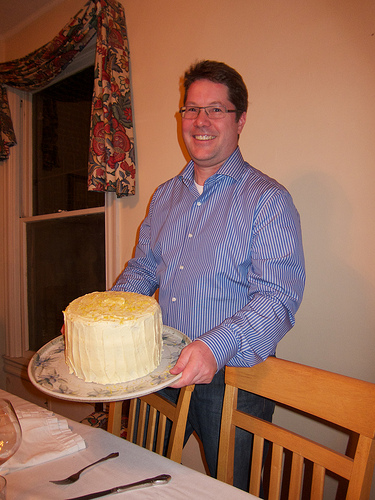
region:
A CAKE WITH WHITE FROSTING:
[52, 281, 176, 388]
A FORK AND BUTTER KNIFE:
[47, 442, 181, 497]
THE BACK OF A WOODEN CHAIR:
[208, 349, 371, 494]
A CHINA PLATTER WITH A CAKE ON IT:
[21, 284, 200, 408]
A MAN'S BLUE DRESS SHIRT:
[104, 147, 309, 377]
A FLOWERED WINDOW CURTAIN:
[6, 5, 137, 204]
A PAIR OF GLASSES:
[175, 99, 247, 125]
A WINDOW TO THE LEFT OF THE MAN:
[6, 137, 126, 360]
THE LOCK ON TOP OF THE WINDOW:
[44, 204, 79, 217]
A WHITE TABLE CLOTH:
[86, 429, 186, 498]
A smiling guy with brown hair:
[139, 57, 291, 287]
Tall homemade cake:
[61, 284, 166, 384]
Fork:
[46, 450, 122, 483]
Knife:
[86, 472, 171, 498]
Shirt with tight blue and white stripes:
[159, 165, 312, 287]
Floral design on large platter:
[31, 352, 65, 388]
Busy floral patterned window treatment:
[75, 6, 136, 136]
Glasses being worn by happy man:
[176, 102, 248, 120]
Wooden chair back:
[224, 362, 352, 498]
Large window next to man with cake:
[19, 45, 110, 350]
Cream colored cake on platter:
[55, 278, 168, 389]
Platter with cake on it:
[21, 308, 211, 404]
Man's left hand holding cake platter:
[167, 324, 224, 399]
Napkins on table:
[20, 407, 89, 467]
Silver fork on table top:
[41, 429, 120, 485]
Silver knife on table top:
[87, 471, 161, 497]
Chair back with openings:
[210, 378, 347, 496]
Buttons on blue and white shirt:
[164, 183, 213, 317]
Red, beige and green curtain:
[65, 6, 159, 213]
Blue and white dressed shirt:
[137, 147, 314, 363]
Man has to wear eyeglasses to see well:
[177, 99, 237, 120]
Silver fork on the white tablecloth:
[45, 444, 120, 486]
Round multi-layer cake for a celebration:
[54, 286, 168, 387]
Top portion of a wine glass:
[0, 396, 23, 475]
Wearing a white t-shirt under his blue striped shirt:
[186, 176, 213, 196]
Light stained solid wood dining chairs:
[217, 356, 372, 499]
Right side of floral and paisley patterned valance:
[89, 4, 134, 196]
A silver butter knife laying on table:
[62, 478, 176, 498]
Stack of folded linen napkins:
[19, 403, 84, 466]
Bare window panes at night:
[32, 94, 98, 284]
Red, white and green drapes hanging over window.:
[0, 2, 145, 198]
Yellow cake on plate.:
[55, 284, 169, 385]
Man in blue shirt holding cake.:
[29, 53, 310, 411]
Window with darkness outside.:
[2, 84, 112, 288]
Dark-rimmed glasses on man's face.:
[175, 86, 240, 128]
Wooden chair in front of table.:
[219, 366, 372, 498]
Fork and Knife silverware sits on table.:
[47, 441, 173, 499]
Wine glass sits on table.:
[0, 386, 25, 499]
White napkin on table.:
[22, 400, 91, 461]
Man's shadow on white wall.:
[307, 166, 356, 361]